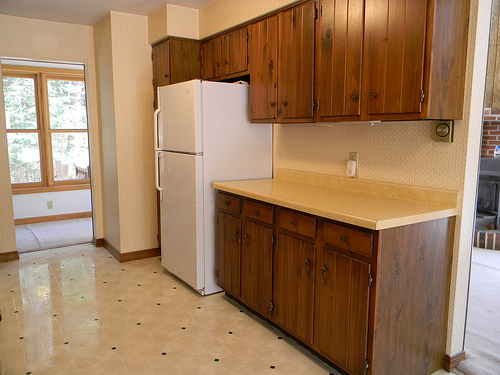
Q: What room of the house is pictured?
A: A kitchen.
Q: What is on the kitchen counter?
A: It is bare.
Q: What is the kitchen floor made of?
A: Tile.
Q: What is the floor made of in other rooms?
A: Carpet.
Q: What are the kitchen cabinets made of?
A: Wood.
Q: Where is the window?
A: In the room on the left.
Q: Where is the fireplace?
A: In the room on the right.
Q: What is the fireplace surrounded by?
A: Brick.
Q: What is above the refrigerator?
A: Wooden cabinets.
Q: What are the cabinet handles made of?
A: Metal.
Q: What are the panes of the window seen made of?
A: Glass.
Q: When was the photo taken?
A: Daytime.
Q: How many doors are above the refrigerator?
A: Two.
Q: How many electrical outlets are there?
A: Two.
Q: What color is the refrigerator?
A: White.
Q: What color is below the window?
A: White.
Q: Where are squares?
A: Floor.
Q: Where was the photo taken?
A: In a kitchen.